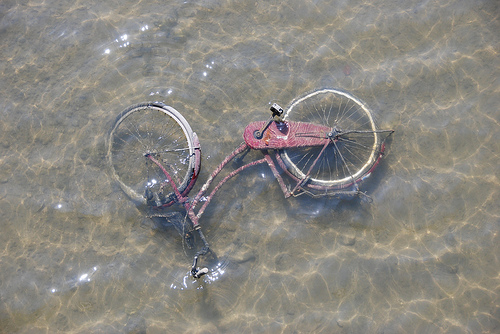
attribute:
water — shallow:
[393, 202, 478, 279]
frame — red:
[137, 113, 404, 280]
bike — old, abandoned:
[104, 88, 398, 303]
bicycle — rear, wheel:
[103, 83, 395, 287]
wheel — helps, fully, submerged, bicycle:
[273, 88, 383, 188]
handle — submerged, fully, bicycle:
[231, 251, 258, 266]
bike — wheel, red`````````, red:
[92, 75, 395, 303]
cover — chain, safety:
[235, 116, 342, 149]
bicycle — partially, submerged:
[87, 69, 406, 294]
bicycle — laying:
[105, 100, 395, 260]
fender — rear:
[289, 172, 375, 202]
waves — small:
[272, 235, 493, 326]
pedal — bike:
[267, 100, 285, 117]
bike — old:
[94, 84, 391, 290]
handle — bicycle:
[176, 262, 219, 290]